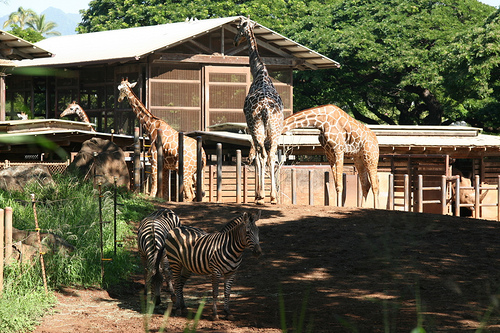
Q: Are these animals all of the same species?
A: No, there are both giraffes and zebras.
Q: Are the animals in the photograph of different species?
A: Yes, they are giraffes and zebras.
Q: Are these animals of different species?
A: Yes, they are giraffes and zebras.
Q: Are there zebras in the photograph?
A: Yes, there is a zebra.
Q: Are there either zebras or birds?
A: Yes, there is a zebra.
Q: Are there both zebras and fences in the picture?
A: Yes, there are both a zebra and a fence.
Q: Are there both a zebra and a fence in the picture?
A: Yes, there are both a zebra and a fence.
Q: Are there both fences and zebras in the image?
A: Yes, there are both a zebra and a fence.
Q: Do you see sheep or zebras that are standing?
A: Yes, the zebra is standing.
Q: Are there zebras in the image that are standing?
A: Yes, there is a zebra that is standing.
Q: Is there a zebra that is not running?
A: Yes, there is a zebra that is standing.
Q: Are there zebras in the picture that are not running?
A: Yes, there is a zebra that is standing.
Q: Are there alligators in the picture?
A: No, there are no alligators.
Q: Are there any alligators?
A: No, there are no alligators.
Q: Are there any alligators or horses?
A: No, there are no alligators or horses.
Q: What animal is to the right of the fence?
A: The animal is a zebra.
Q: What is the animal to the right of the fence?
A: The animal is a zebra.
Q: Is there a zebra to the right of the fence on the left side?
A: Yes, there is a zebra to the right of the fence.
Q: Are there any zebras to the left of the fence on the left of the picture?
A: No, the zebra is to the right of the fence.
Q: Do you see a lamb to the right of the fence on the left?
A: No, there is a zebra to the right of the fence.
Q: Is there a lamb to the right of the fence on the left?
A: No, there is a zebra to the right of the fence.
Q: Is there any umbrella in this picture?
A: No, there are no umbrellas.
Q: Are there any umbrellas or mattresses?
A: No, there are no umbrellas or mattresses.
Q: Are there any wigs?
A: No, there are no wigs.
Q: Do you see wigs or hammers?
A: No, there are no wigs or hammers.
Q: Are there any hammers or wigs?
A: No, there are no wigs or hammers.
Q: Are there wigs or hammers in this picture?
A: No, there are no wigs or hammers.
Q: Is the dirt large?
A: Yes, the dirt is large.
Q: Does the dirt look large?
A: Yes, the dirt is large.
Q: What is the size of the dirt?
A: The dirt is large.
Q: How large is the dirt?
A: The dirt is large.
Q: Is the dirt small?
A: No, the dirt is large.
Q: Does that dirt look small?
A: No, the dirt is large.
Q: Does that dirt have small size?
A: No, the dirt is large.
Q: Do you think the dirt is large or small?
A: The dirt is large.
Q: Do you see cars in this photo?
A: No, there are no cars.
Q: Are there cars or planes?
A: No, there are no cars or planes.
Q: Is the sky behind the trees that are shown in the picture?
A: Yes, the sky is behind the trees.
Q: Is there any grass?
A: Yes, there is grass.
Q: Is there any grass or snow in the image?
A: Yes, there is grass.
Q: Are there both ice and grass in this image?
A: No, there is grass but no ice.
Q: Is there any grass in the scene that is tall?
A: Yes, there is tall grass.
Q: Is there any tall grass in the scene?
A: Yes, there is tall grass.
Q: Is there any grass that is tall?
A: Yes, there is grass that is tall.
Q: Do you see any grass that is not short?
A: Yes, there is tall grass.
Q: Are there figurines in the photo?
A: No, there are no figurines.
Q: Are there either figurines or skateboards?
A: No, there are no figurines or skateboards.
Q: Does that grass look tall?
A: Yes, the grass is tall.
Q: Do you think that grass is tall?
A: Yes, the grass is tall.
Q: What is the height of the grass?
A: The grass is tall.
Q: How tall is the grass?
A: The grass is tall.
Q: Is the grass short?
A: No, the grass is tall.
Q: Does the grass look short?
A: No, the grass is tall.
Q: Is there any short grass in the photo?
A: No, there is grass but it is tall.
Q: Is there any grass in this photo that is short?
A: No, there is grass but it is tall.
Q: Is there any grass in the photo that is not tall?
A: No, there is grass but it is tall.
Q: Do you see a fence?
A: Yes, there is a fence.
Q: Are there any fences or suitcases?
A: Yes, there is a fence.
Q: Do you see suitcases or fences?
A: Yes, there is a fence.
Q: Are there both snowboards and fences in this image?
A: No, there is a fence but no snowboards.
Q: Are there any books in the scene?
A: No, there are no books.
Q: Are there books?
A: No, there are no books.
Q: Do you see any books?
A: No, there are no books.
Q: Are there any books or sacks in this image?
A: No, there are no books or sacks.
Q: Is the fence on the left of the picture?
A: Yes, the fence is on the left of the image.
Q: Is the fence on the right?
A: No, the fence is on the left of the image.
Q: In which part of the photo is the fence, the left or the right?
A: The fence is on the left of the image.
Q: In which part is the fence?
A: The fence is on the left of the image.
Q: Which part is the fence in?
A: The fence is on the left of the image.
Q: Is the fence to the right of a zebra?
A: No, the fence is to the left of a zebra.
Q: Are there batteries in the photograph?
A: No, there are no batteries.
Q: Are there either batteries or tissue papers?
A: No, there are no batteries or tissue papers.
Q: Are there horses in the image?
A: No, there are no horses.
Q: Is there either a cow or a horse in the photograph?
A: No, there are no horses or cows.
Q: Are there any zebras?
A: Yes, there are zebras.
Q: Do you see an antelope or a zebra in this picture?
A: Yes, there are zebras.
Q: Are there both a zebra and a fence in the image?
A: Yes, there are both a zebra and a fence.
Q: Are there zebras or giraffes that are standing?
A: Yes, the zebras are standing.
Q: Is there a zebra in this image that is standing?
A: Yes, there are zebras that are standing.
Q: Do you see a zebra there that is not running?
A: Yes, there are zebras that are standing .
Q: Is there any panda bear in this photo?
A: No, there are no panda bears.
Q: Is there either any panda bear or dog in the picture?
A: No, there are no panda bears or dogs.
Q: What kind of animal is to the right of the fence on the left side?
A: The animals are zebras.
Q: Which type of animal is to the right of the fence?
A: The animals are zebras.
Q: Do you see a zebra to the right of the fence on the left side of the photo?
A: Yes, there are zebras to the right of the fence.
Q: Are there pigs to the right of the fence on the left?
A: No, there are zebras to the right of the fence.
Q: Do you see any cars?
A: No, there are no cars.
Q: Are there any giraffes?
A: Yes, there is a giraffe.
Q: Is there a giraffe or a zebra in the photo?
A: Yes, there is a giraffe.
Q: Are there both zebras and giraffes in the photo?
A: Yes, there are both a giraffe and a zebra.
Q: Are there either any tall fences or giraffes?
A: Yes, there is a tall giraffe.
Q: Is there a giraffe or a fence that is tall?
A: Yes, the giraffe is tall.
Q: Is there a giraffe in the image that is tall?
A: Yes, there is a tall giraffe.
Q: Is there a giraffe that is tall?
A: Yes, there is a giraffe that is tall.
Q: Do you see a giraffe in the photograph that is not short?
A: Yes, there is a tall giraffe.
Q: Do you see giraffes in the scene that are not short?
A: Yes, there is a tall giraffe.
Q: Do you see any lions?
A: No, there are no lions.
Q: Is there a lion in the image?
A: No, there are no lions.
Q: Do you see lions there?
A: No, there are no lions.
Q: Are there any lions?
A: No, there are no lions.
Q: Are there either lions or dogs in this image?
A: No, there are no lions or dogs.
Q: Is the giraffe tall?
A: Yes, the giraffe is tall.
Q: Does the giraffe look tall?
A: Yes, the giraffe is tall.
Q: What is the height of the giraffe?
A: The giraffe is tall.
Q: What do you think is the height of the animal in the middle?
A: The giraffe is tall.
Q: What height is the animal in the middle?
A: The giraffe is tall.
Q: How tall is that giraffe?
A: The giraffe is tall.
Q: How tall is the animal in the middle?
A: The giraffe is tall.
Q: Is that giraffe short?
A: No, the giraffe is tall.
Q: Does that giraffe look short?
A: No, the giraffe is tall.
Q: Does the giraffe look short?
A: No, the giraffe is tall.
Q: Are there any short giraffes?
A: No, there is a giraffe but it is tall.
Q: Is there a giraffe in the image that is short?
A: No, there is a giraffe but it is tall.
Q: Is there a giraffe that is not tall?
A: No, there is a giraffe but it is tall.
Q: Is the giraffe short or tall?
A: The giraffe is tall.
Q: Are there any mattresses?
A: No, there are no mattresses.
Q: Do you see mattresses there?
A: No, there are no mattresses.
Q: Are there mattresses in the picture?
A: No, there are no mattresses.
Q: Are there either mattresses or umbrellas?
A: No, there are no mattresses or umbrellas.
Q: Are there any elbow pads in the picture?
A: No, there are no elbow pads.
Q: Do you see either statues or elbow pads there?
A: No, there are no elbow pads or statues.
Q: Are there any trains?
A: No, there are no trains.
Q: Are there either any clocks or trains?
A: No, there are no trains or clocks.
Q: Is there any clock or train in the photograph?
A: No, there are no trains or clocks.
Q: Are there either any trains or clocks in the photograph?
A: No, there are no trains or clocks.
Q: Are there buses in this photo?
A: No, there are no buses.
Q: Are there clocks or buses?
A: No, there are no buses or clocks.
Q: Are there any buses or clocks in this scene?
A: No, there are no buses or clocks.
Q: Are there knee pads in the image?
A: No, there are no knee pads.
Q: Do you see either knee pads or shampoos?
A: No, there are no knee pads or shampoos.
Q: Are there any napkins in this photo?
A: No, there are no napkins.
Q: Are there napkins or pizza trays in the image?
A: No, there are no napkins or pizza trays.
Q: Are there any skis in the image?
A: No, there are no skis.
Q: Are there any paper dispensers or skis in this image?
A: No, there are no skis or paper dispensers.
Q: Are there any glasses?
A: No, there are no glasses.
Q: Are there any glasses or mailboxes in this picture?
A: No, there are no glasses or mailboxes.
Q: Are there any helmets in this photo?
A: No, there are no helmets.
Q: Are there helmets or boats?
A: No, there are no helmets or boats.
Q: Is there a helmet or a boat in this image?
A: No, there are no helmets or boats.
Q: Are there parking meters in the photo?
A: No, there are no parking meters.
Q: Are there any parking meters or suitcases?
A: No, there are no parking meters or suitcases.